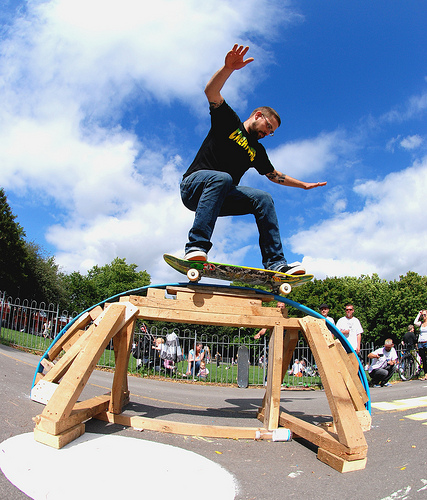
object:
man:
[179, 43, 327, 276]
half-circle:
[29, 281, 372, 474]